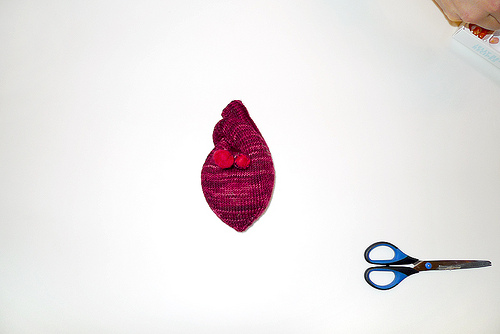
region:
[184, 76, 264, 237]
a shape of heart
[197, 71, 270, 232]
the cloth is knitted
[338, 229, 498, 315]
a pair of scissors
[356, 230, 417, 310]
the handle is blue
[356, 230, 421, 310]
the handle is brown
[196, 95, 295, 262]
the cloth is red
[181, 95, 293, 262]
the cloth is stripes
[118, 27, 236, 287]
the background is white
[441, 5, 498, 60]
a hand on the table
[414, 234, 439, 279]
the screw is blue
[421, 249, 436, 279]
Blue button on scissors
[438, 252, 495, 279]
Long part of scissors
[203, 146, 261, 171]
Light pink balls on pouch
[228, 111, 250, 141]
Plaid pattern on pouch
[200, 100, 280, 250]
Burgandy and pink pouch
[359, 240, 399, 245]
Black outline on scissors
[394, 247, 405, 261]
Blue color on scissors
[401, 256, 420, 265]
Black color on scissors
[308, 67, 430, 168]
Top of white table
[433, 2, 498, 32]
Top of person's hand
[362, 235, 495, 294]
pair of blue and black scissors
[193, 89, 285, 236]
red knitted cap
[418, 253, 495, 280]
blade of a pair of scissors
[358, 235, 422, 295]
blue and black scissor handles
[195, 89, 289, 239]
a red knitted hat of some sort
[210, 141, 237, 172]
decorative red ball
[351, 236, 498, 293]
pair of scissors on a table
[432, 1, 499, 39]
knuckles and fingers of a hand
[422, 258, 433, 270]
small blue nut on a pair of scissors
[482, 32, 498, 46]
a small pink button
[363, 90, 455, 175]
A white background.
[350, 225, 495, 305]
A pair of scissors.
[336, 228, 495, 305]
The scissors are blue.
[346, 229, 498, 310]
The scissors are made of metal and plastic.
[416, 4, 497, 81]
A hand is in the corner.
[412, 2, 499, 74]
The hand is holding something.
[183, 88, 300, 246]
Something red is in the middle of the photo.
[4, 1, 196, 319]
The photo is mostly empty space.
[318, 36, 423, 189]
The background is really white.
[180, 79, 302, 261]
This is the focus of the picture.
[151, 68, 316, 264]
a knitted project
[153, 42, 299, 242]
a purple item on table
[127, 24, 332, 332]
a purple item on white table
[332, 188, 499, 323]
blue and black scissors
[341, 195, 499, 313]
scissors on white table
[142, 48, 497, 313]
scissors and purple bag on table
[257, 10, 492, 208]
a white table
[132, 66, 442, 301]
a purple pouch laying down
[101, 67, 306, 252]
a white table with purple pouch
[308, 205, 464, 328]
a white table with scissors